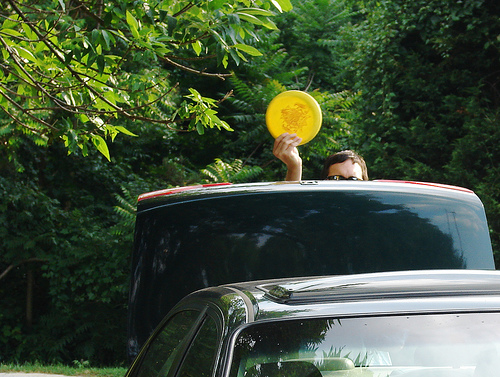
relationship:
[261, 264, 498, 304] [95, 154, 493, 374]
sunroof on car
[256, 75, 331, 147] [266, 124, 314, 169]
frisbee in hand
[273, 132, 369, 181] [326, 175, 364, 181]
catcher wears glasses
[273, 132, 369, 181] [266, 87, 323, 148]
catcher holds frisbee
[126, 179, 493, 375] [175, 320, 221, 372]
car has window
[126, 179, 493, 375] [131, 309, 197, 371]
car has window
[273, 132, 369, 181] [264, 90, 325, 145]
catcher has frisbee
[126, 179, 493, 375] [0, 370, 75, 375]
car on road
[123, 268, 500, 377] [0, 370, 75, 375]
car on road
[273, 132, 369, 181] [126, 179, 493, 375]
catcher inside car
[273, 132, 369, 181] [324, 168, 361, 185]
catcher wears glasses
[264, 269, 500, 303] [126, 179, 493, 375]
sunroof on car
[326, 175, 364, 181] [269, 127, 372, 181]
glasses on man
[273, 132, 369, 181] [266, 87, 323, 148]
catcher holding frisbee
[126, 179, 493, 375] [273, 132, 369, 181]
car with catcher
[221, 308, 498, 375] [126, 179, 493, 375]
windshield on car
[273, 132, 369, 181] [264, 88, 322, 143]
catcher holding frisbee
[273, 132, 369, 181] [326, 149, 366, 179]
catcher has hair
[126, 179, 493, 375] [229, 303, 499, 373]
car has windshield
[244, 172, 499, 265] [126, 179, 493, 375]
reflection on car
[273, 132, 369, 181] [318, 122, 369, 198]
catcher has head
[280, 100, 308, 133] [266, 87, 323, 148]
design on frisbee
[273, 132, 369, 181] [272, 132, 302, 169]
catcher has hand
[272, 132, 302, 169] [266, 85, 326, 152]
hand holding frisbee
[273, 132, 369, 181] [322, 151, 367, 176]
catcher has hair